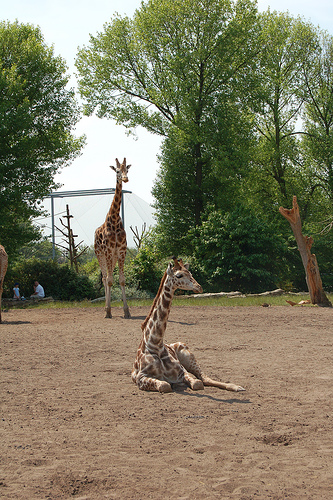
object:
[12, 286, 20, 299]
shirt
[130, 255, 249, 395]
giraffe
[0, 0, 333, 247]
clouds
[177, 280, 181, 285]
spots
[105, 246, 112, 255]
spot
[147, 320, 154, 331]
spot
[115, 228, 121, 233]
spot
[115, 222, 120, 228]
spot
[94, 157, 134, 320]
giraffe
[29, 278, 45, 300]
man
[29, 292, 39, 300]
pants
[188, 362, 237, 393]
legs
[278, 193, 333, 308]
trunk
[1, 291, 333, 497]
ground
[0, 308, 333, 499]
dirt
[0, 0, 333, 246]
sky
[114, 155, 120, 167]
ossicles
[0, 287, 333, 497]
field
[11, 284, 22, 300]
girl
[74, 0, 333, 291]
trees